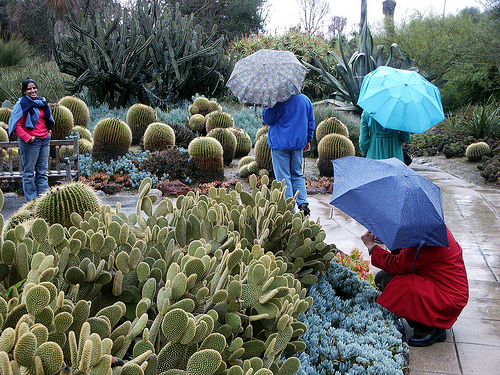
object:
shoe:
[410, 322, 447, 348]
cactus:
[465, 142, 490, 164]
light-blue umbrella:
[356, 65, 445, 134]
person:
[261, 93, 314, 215]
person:
[360, 227, 469, 348]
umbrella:
[225, 48, 305, 108]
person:
[358, 108, 411, 166]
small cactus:
[189, 113, 204, 131]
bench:
[0, 137, 82, 181]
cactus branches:
[50, 0, 235, 109]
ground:
[404, 178, 500, 375]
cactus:
[160, 308, 188, 346]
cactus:
[315, 132, 355, 173]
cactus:
[187, 136, 224, 176]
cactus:
[90, 117, 134, 162]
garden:
[0, 0, 500, 375]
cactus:
[143, 122, 176, 150]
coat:
[371, 229, 469, 330]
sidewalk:
[0, 156, 498, 371]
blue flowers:
[292, 255, 412, 375]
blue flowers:
[74, 151, 169, 187]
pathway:
[446, 178, 488, 240]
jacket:
[262, 94, 315, 151]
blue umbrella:
[327, 156, 450, 252]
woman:
[9, 78, 55, 204]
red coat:
[356, 218, 480, 330]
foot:
[408, 326, 447, 346]